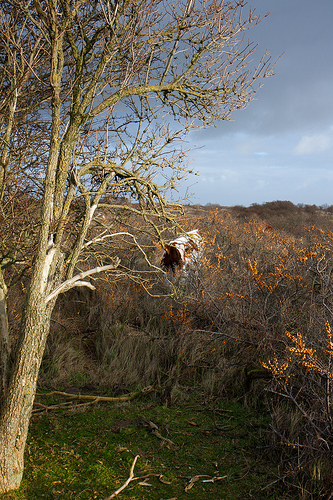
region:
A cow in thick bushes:
[141, 223, 217, 294]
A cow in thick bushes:
[142, 221, 216, 290]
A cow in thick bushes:
[151, 220, 214, 289]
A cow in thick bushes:
[151, 224, 214, 292]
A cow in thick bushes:
[149, 220, 213, 295]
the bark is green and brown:
[2, 297, 55, 488]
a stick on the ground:
[110, 454, 140, 498]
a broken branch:
[34, 384, 151, 407]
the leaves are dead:
[261, 355, 289, 377]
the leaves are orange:
[265, 324, 331, 391]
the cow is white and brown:
[159, 229, 203, 274]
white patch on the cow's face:
[175, 242, 185, 258]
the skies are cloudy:
[150, 1, 326, 200]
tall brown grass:
[44, 307, 226, 385]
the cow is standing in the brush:
[156, 222, 203, 279]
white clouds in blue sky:
[191, 146, 224, 185]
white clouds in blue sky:
[276, 147, 331, 193]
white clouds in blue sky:
[208, 145, 233, 185]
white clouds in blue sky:
[235, 170, 254, 189]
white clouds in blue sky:
[278, 131, 310, 179]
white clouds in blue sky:
[277, 17, 315, 55]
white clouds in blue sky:
[267, 143, 310, 175]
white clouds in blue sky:
[215, 135, 258, 168]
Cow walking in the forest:
[142, 199, 214, 294]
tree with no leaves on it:
[37, 33, 166, 282]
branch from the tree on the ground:
[99, 449, 168, 496]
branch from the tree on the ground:
[46, 385, 156, 413]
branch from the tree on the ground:
[171, 459, 222, 496]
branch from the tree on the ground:
[130, 407, 198, 468]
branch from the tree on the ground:
[146, 459, 170, 491]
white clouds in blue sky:
[254, 55, 271, 95]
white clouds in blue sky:
[291, 169, 314, 187]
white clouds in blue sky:
[229, 163, 250, 179]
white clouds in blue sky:
[224, 168, 276, 202]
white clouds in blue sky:
[277, 112, 311, 151]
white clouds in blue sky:
[214, 145, 249, 173]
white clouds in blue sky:
[200, 135, 227, 174]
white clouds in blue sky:
[251, 153, 280, 177]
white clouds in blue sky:
[261, 68, 316, 107]